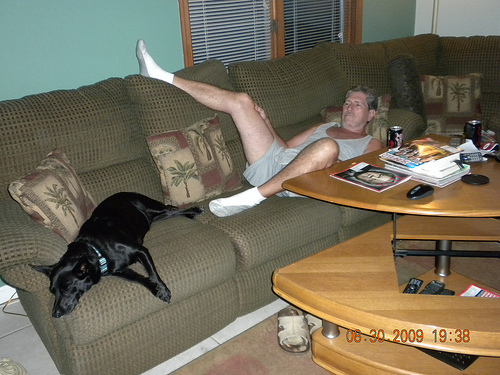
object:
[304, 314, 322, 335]
shoe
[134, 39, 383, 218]
man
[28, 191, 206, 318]
dog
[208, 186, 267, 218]
sock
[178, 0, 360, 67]
window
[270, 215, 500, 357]
table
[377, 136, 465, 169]
magazine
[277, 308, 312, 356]
shoe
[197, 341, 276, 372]
floor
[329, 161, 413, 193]
magazine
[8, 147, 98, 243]
pillow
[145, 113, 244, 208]
pillow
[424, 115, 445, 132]
pillow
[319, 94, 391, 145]
pillow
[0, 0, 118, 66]
wall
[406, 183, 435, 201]
mouse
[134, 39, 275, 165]
foot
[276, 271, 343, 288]
wood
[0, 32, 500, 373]
couch